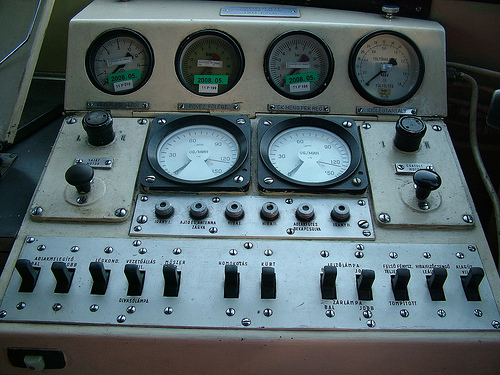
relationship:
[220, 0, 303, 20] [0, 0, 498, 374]
panel on top of control panel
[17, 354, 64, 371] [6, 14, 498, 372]
button on bottom of machine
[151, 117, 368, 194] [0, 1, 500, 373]
dial instruments in console center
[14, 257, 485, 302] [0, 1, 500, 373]
row of console center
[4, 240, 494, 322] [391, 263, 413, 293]
panel of knobs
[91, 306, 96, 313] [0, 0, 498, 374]
bolt on control panel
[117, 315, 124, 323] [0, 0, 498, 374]
bolt on control panel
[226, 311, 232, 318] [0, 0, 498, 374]
bolt on control panel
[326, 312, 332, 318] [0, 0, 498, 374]
bolt on control panel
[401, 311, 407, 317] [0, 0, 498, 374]
bolt on control panel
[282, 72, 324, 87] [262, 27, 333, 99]
green sticker on front control gauge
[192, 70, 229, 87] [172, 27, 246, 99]
green sticker on front control gauge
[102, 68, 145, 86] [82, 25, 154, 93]
green sticker on front control gauge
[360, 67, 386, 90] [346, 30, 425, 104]
needle in control gauge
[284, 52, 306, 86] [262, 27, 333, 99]
needle in control gauge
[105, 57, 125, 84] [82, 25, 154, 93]
needle in control gauge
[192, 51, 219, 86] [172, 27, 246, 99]
needle in control gauge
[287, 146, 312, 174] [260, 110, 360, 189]
needle in control gauge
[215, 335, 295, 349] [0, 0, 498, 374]
specks on front control panel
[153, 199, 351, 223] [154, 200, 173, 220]
row of six indicator lights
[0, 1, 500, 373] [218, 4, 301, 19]
console center information label